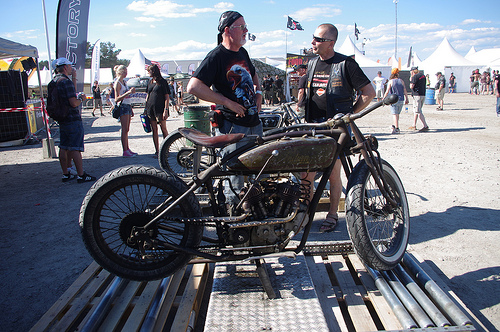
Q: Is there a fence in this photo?
A: No, there are no fences.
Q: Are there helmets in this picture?
A: No, there are no helmets.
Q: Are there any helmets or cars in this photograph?
A: No, there are no helmets or cars.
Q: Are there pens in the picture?
A: No, there are no pens.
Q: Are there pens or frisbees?
A: No, there are no pens or frisbees.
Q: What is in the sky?
A: The clouds are in the sky.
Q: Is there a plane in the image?
A: No, there are no airplanes.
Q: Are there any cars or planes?
A: No, there are no planes or cars.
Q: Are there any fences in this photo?
A: No, there are no fences.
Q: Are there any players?
A: No, there are no players.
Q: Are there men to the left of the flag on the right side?
A: Yes, there is a man to the left of the flag.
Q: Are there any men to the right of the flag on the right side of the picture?
A: No, the man is to the left of the flag.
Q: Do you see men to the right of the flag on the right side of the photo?
A: No, the man is to the left of the flag.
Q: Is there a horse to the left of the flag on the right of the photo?
A: No, there is a man to the left of the flag.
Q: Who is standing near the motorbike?
A: The man is standing near the motorbike.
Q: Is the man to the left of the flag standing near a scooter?
A: No, the man is standing near the motorcycle.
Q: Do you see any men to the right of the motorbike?
A: No, the man is to the left of the motorbike.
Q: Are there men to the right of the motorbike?
A: No, the man is to the left of the motorbike.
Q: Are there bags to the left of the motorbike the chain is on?
A: No, there is a man to the left of the motorcycle.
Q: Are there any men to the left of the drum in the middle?
A: Yes, there is a man to the left of the drum.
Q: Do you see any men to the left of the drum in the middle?
A: Yes, there is a man to the left of the drum.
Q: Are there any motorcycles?
A: Yes, there is a motorcycle.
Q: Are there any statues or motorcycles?
A: Yes, there is a motorcycle.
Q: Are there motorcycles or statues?
A: Yes, there is a motorcycle.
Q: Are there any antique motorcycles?
A: Yes, there is an antique motorcycle.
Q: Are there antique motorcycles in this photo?
A: Yes, there is an antique motorcycle.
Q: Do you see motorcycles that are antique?
A: Yes, there is a motorcycle that is antique.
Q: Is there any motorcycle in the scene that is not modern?
A: Yes, there is a antique motorcycle.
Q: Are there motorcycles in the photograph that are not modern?
A: Yes, there is a antique motorcycle.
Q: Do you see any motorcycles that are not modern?
A: Yes, there is a antique motorcycle.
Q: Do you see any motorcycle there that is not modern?
A: Yes, there is a antique motorcycle.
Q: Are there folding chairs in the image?
A: No, there are no folding chairs.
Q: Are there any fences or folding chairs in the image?
A: No, there are no folding chairs or fences.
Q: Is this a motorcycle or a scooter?
A: This is a motorcycle.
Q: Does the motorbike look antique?
A: Yes, the motorbike is antique.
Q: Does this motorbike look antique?
A: Yes, the motorbike is antique.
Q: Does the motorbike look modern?
A: No, the motorbike is antique.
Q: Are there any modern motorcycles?
A: No, there is a motorcycle but it is antique.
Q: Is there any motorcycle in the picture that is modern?
A: No, there is a motorcycle but it is antique.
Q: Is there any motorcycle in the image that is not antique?
A: No, there is a motorcycle but it is antique.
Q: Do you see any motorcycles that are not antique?
A: No, there is a motorcycle but it is antique.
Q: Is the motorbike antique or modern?
A: The motorbike is antique.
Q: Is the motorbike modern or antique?
A: The motorbike is antique.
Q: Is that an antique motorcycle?
A: Yes, that is an antique motorcycle.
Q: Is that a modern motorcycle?
A: No, that is an antique motorcycle.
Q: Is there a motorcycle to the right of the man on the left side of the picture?
A: Yes, there is a motorcycle to the right of the man.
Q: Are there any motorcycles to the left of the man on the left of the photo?
A: No, the motorcycle is to the right of the man.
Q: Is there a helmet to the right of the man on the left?
A: No, there is a motorcycle to the right of the man.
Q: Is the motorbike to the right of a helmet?
A: No, the motorbike is to the right of a man.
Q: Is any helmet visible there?
A: No, there are no helmets.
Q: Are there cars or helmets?
A: No, there are no helmets or cars.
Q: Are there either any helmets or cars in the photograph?
A: No, there are no helmets or cars.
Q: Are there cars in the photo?
A: No, there are no cars.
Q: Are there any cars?
A: No, there are no cars.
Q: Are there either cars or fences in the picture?
A: No, there are no cars or fences.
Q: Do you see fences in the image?
A: No, there are no fences.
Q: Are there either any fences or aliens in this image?
A: No, there are no fences or aliens.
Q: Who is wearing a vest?
A: The man is wearing a vest.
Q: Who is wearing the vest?
A: The man is wearing a vest.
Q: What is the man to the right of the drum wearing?
A: The man is wearing a vest.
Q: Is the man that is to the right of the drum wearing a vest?
A: Yes, the man is wearing a vest.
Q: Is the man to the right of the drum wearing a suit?
A: No, the man is wearing a vest.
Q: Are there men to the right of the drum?
A: Yes, there is a man to the right of the drum.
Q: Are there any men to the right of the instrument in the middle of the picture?
A: Yes, there is a man to the right of the drum.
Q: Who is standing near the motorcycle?
A: The man is standing near the motorcycle.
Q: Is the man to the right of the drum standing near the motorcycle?
A: Yes, the man is standing near the motorcycle.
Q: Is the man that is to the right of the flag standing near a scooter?
A: No, the man is standing near the motorcycle.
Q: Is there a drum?
A: Yes, there is a drum.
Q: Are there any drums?
A: Yes, there is a drum.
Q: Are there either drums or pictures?
A: Yes, there is a drum.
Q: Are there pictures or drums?
A: Yes, there is a drum.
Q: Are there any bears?
A: No, there are no bears.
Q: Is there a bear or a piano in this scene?
A: No, there are no bears or pianoes.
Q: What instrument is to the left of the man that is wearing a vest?
A: The instrument is a drum.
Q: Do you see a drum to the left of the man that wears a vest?
A: Yes, there is a drum to the left of the man.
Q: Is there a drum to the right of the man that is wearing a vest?
A: No, the drum is to the left of the man.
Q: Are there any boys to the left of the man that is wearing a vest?
A: No, there is a drum to the left of the man.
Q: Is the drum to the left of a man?
A: Yes, the drum is to the left of a man.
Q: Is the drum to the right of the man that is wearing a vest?
A: No, the drum is to the left of the man.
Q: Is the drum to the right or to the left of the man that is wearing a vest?
A: The drum is to the left of the man.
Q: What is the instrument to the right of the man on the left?
A: The instrument is a drum.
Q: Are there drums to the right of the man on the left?
A: Yes, there is a drum to the right of the man.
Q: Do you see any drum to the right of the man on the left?
A: Yes, there is a drum to the right of the man.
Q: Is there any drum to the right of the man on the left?
A: Yes, there is a drum to the right of the man.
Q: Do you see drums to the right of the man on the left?
A: Yes, there is a drum to the right of the man.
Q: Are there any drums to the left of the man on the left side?
A: No, the drum is to the right of the man.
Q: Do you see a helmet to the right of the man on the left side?
A: No, there is a drum to the right of the man.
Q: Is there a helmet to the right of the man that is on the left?
A: No, there is a drum to the right of the man.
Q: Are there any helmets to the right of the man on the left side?
A: No, there is a drum to the right of the man.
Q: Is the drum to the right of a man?
A: Yes, the drum is to the right of a man.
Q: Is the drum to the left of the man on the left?
A: No, the drum is to the right of the man.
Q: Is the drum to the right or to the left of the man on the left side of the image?
A: The drum is to the right of the man.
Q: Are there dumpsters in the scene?
A: No, there are no dumpsters.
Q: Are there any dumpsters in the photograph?
A: No, there are no dumpsters.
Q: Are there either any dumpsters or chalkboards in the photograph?
A: No, there are no dumpsters or chalkboards.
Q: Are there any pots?
A: No, there are no pots.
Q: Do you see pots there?
A: No, there are no pots.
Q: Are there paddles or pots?
A: No, there are no pots or paddles.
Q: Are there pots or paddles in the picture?
A: No, there are no pots or paddles.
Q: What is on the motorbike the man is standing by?
A: The chain is on the motorcycle.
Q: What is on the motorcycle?
A: The chain is on the motorcycle.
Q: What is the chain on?
A: The chain is on the motorcycle.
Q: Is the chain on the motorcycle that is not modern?
A: Yes, the chain is on the motorcycle.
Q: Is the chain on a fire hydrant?
A: No, the chain is on the motorcycle.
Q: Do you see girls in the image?
A: No, there are no girls.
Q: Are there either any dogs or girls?
A: No, there are no girls or dogs.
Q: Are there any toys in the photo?
A: No, there are no toys.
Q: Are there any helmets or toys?
A: No, there are no toys or helmets.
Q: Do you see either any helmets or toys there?
A: No, there are no toys or helmets.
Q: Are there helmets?
A: No, there are no helmets.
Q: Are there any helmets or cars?
A: No, there are no helmets or cars.